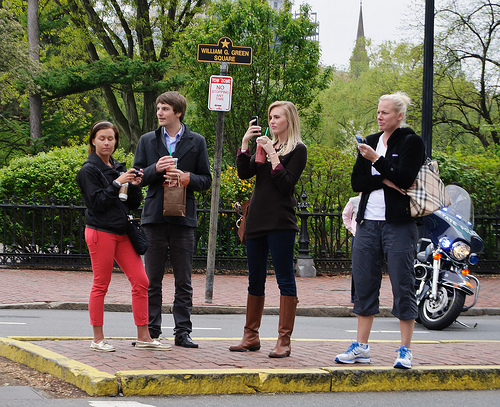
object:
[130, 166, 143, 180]
cellphone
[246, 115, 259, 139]
phone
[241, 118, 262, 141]
hand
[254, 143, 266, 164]
cup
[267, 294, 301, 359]
boot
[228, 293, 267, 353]
boot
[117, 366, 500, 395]
side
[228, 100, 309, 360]
person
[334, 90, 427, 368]
person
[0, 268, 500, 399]
sidewalk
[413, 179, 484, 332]
motorcycle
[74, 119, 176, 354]
pedestrian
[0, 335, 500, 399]
median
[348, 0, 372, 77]
building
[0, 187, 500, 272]
fence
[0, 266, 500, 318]
sidewalk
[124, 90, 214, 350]
pedestrian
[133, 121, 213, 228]
coat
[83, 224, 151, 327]
jeans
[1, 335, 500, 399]
meridian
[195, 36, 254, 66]
sign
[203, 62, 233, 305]
pole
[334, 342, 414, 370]
sneakers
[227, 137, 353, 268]
bush